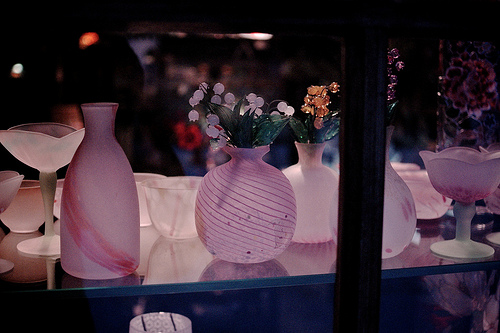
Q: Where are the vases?
A: On a shelf.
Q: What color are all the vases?
A: Pink.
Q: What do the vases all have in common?
A: Colored pink.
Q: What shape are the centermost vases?
A: Round.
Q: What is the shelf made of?
A: Glass.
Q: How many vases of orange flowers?
A: One.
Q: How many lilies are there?
A: None.